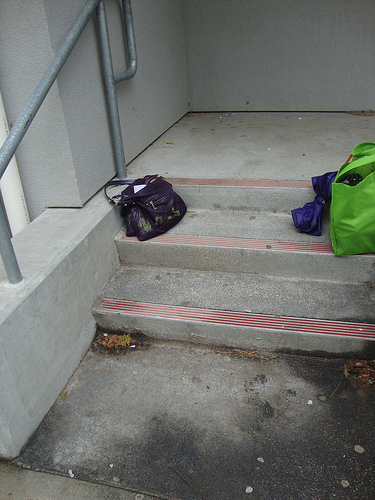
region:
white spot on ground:
[352, 441, 364, 455]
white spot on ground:
[339, 478, 350, 487]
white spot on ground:
[306, 397, 315, 405]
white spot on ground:
[256, 455, 266, 466]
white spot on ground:
[244, 485, 254, 495]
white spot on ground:
[111, 472, 127, 485]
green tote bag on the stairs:
[323, 140, 373, 262]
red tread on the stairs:
[99, 175, 373, 338]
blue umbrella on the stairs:
[289, 172, 330, 235]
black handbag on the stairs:
[102, 169, 183, 240]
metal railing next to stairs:
[4, 2, 137, 280]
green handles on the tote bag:
[338, 134, 374, 175]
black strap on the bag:
[102, 176, 129, 204]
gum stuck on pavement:
[212, 395, 362, 498]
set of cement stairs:
[88, 168, 374, 356]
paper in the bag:
[128, 181, 145, 193]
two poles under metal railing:
[1, 1, 137, 281]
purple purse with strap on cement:
[102, 174, 186, 241]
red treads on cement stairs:
[93, 176, 373, 354]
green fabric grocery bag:
[331, 140, 373, 254]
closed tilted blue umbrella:
[285, 155, 352, 236]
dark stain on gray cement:
[21, 340, 374, 498]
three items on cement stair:
[102, 141, 373, 255]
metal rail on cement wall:
[0, 0, 136, 458]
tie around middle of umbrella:
[288, 153, 349, 235]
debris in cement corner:
[87, 316, 136, 350]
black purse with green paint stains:
[106, 168, 190, 243]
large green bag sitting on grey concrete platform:
[326, 136, 373, 254]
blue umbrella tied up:
[289, 163, 343, 239]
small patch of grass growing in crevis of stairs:
[90, 330, 136, 355]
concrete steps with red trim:
[10, 167, 368, 481]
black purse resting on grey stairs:
[100, 172, 187, 242]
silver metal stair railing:
[1, 0, 140, 284]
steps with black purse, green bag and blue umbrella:
[84, 133, 374, 361]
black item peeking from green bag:
[335, 172, 363, 187]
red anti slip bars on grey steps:
[94, 294, 374, 341]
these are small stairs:
[27, 41, 333, 382]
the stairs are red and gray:
[196, 188, 258, 346]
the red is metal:
[139, 293, 222, 327]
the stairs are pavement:
[172, 257, 249, 303]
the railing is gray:
[19, 46, 86, 118]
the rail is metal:
[39, 15, 129, 107]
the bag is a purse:
[107, 160, 176, 225]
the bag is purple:
[109, 173, 222, 269]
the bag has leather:
[107, 185, 219, 236]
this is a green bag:
[323, 190, 370, 263]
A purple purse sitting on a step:
[113, 171, 196, 240]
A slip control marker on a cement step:
[102, 295, 359, 339]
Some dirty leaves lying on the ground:
[95, 326, 142, 353]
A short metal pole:
[107, 116, 131, 180]